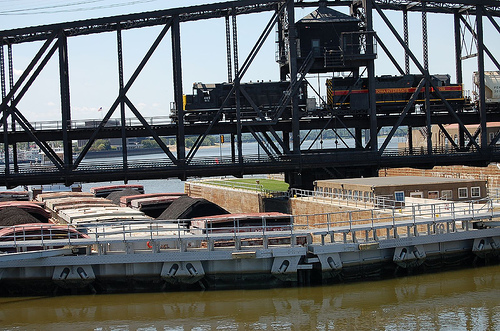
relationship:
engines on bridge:
[324, 72, 466, 118] [2, 3, 496, 194]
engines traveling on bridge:
[324, 72, 466, 118] [14, 5, 487, 149]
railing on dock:
[0, 198, 499, 255] [2, 196, 499, 289]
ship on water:
[82, 144, 166, 159] [80, 131, 432, 177]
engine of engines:
[166, 72, 318, 131] [324, 72, 466, 118]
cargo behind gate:
[9, 177, 296, 271] [3, 213, 428, 252]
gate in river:
[3, 213, 428, 252] [18, 286, 478, 328]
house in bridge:
[280, 3, 377, 74] [2, 3, 496, 194]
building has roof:
[303, 170, 493, 209] [317, 175, 487, 186]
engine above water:
[167, 79, 309, 124] [5, 132, 407, 164]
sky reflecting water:
[3, 9, 498, 183] [316, 299, 370, 328]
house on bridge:
[280, 3, 377, 74] [5, 25, 496, 158]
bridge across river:
[0, 0, 499, 189] [0, 128, 497, 331]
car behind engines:
[88, 199, 140, 244] [168, 67, 472, 131]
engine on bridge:
[167, 79, 309, 124] [42, 14, 497, 131]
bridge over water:
[2, 3, 496, 194] [16, 132, 430, 193]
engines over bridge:
[324, 72, 466, 118] [5, 25, 496, 158]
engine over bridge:
[167, 79, 309, 124] [5, 25, 496, 158]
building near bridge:
[384, 117, 498, 162] [0, 0, 499, 189]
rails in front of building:
[235, 169, 363, 210] [389, 118, 499, 168]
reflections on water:
[50, 287, 324, 318] [297, 291, 423, 319]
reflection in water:
[154, 307, 446, 325] [18, 254, 494, 329]